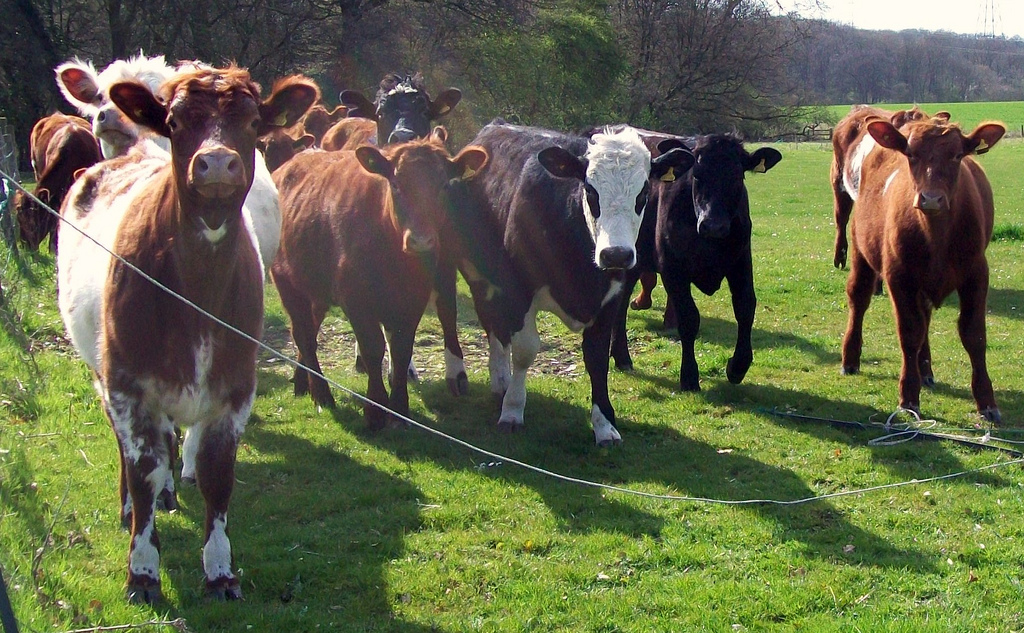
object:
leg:
[101, 383, 170, 606]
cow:
[58, 48, 318, 603]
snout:
[187, 145, 245, 199]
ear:
[109, 80, 167, 137]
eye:
[165, 116, 184, 131]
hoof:
[591, 419, 623, 449]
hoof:
[496, 400, 528, 432]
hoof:
[121, 564, 167, 610]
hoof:
[203, 575, 242, 602]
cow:
[833, 105, 1006, 426]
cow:
[269, 135, 486, 431]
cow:
[457, 116, 693, 446]